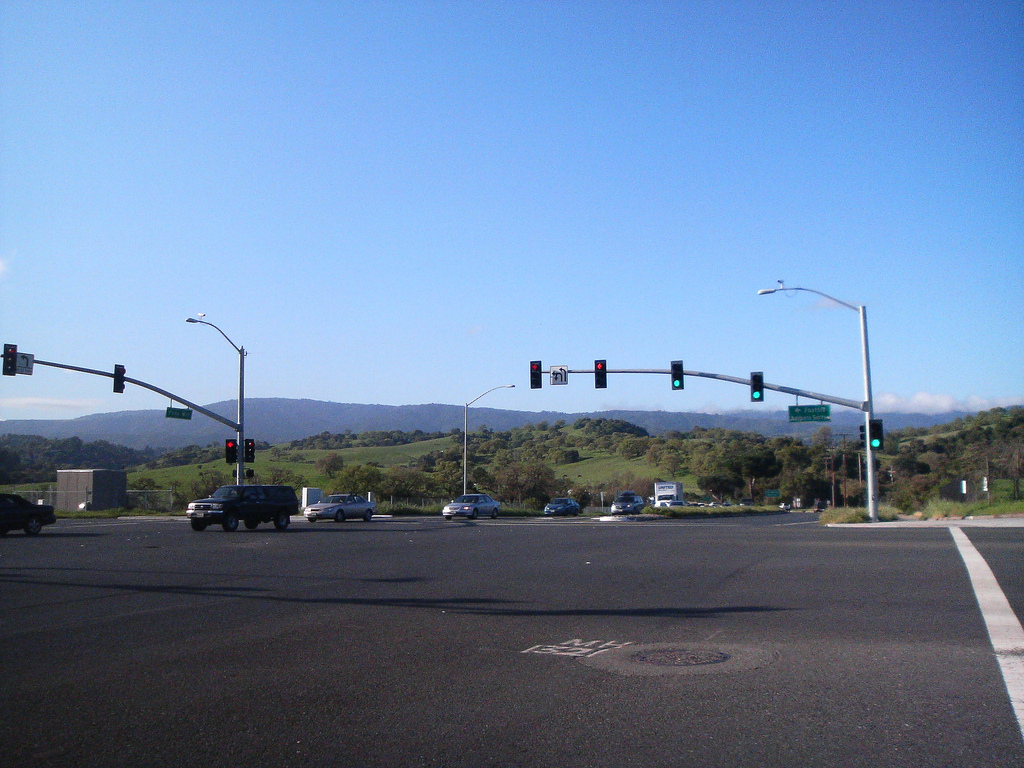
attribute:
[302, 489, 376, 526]
car — on a street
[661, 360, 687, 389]
signal light — green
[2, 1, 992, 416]
sky — cloudless, blue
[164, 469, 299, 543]
vehicle — black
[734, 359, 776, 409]
signal light — green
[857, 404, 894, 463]
signal light — green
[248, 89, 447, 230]
sky — blue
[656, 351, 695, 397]
traffic lights — green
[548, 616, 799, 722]
marking — white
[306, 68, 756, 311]
sky — clear, blue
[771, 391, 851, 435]
street sign — green, white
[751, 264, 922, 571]
pole — tall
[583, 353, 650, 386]
traffic signal — red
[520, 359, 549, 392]
traffic signal — red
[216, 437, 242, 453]
traffic signal — red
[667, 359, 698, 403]
traffic signal — green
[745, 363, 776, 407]
traffic signal — green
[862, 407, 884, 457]
traffic signal — green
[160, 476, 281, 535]
suv — black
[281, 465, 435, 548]
car — silver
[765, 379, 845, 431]
street sign — green, white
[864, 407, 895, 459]
traffic signal — electric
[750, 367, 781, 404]
traffic signal — electric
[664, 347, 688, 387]
traffic signal — electric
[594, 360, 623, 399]
traffic signal — electric